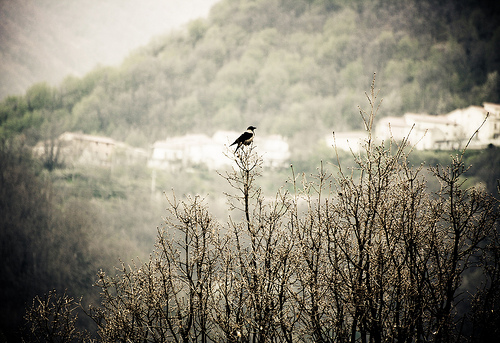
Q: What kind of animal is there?
A: Bird.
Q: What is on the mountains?
A: Trees.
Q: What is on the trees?
A: Green leaves.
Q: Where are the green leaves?
A: On tree.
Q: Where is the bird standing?
A: On bare tree.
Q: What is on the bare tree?
A: Bird.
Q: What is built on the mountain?
A: Houses.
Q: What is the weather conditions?
A: Foggy.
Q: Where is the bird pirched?
A: Atop a tree.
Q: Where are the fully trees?
A: Behind the house.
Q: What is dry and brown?
A: Brush.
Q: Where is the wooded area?
A: Behind the bird.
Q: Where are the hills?
A: Along the trail.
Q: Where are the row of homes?
A: In the valley.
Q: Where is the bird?
A: On the branch.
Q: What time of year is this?
A: Winter.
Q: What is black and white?
A: Bird.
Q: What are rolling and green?
A: Hills.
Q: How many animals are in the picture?
A: One.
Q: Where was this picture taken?
A: In the mountains.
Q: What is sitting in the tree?
A: A bird.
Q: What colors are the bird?
A: Black and white.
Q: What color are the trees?
A: Green.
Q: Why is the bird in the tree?
A: It lives there.